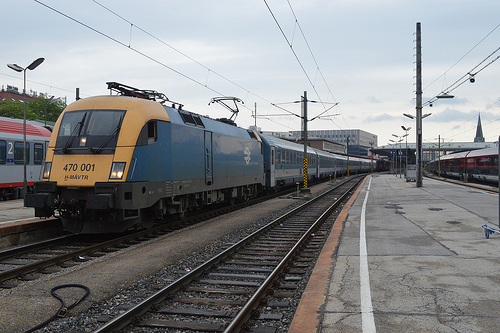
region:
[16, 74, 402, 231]
black and yellow train on tracks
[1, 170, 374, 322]
black metal tracks at railway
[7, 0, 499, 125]
electrical wires in sky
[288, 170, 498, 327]
grey concrete platform with painted white lines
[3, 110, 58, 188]
red and grey train in background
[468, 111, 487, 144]
pointed spire in distance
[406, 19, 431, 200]
tall wooden electrical pole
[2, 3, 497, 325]
this is an outdoor railway scene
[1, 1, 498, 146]
clear blue sky with some clouds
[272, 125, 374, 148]
square yellow stone building in distance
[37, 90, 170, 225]
the front of the train engine is yellow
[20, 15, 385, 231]
the train on the tracks is electrified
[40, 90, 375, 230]
the train engine is pulling passenger cars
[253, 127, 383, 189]
the train passenger cars are blue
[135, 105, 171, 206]
the window is open on the engine train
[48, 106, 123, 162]
the engine front windows have windshield wipers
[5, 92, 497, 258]
three trains are at the station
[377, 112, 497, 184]
a steeple is behind the station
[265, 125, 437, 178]
a building is near the station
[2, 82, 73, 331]
green foliage is growing near the tracks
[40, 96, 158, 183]
the face of the train is yellow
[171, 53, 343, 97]
there are electrical lines above the train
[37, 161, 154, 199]
the lights are on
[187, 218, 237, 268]
there are gravel between the tracks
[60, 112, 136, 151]
the train has two windows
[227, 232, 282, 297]
the track has wood betwwen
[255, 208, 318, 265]
the rail is metaalic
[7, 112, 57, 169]
the train has a red top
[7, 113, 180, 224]
there are two trains on the track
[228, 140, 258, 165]
there is a logo on the side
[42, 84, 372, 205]
commuter train on track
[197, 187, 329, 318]
train tracks next to platform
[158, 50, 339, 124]
wires above train and tracks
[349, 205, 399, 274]
white line on cement platform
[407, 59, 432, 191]
pole in cement platform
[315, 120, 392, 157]
building with flat roof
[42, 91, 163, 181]
yellow front of train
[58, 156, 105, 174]
numbers on front of train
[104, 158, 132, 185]
light on front of train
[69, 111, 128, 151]
windshield wipers on train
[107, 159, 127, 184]
front headlight of a train.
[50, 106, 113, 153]
front windhshield of train.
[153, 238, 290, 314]
railings of train tracks.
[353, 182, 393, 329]
white line on the pavement.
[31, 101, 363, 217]
a large train on tracks.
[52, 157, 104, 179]
numbers reading 470 001 on a train.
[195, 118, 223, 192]
a side door area on train.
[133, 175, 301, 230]
wheel section of a train.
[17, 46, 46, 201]
a tall lamp post outside a station.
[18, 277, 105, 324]
a black cable on the ground.